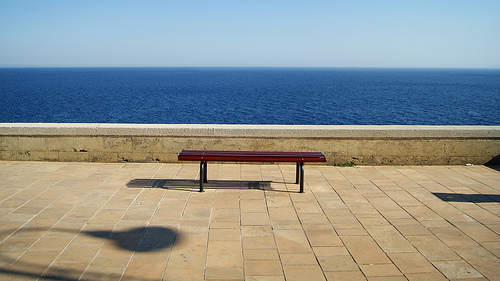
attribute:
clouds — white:
[323, 27, 438, 60]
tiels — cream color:
[365, 202, 442, 252]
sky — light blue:
[3, 0, 497, 77]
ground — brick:
[3, 158, 498, 278]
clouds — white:
[117, 25, 359, 62]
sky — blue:
[88, 8, 459, 68]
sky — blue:
[6, 6, 491, 93]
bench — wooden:
[174, 148, 331, 186]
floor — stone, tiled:
[200, 200, 434, 279]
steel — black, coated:
[186, 157, 329, 198]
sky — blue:
[138, 12, 251, 47]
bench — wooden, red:
[173, 142, 329, 197]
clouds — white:
[58, 28, 423, 60]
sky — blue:
[1, 6, 483, 69]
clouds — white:
[0, 6, 455, 59]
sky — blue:
[0, 2, 480, 63]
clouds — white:
[0, 1, 467, 61]